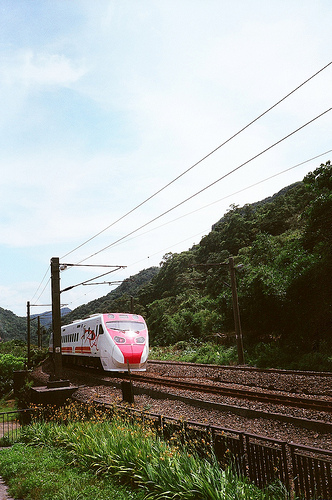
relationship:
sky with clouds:
[4, 7, 302, 143] [17, 43, 98, 95]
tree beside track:
[235, 240, 316, 346] [168, 353, 330, 437]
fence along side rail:
[80, 399, 330, 495] [139, 370, 330, 422]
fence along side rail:
[0, 399, 332, 499] [64, 359, 155, 384]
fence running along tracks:
[0, 399, 332, 499] [158, 361, 319, 431]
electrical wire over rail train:
[58, 57, 331, 265] [49, 312, 149, 371]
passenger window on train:
[65, 327, 80, 343] [28, 303, 149, 375]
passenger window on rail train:
[62, 331, 80, 343] [153, 369, 219, 410]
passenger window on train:
[62, 331, 80, 343] [49, 313, 149, 373]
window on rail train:
[105, 321, 144, 331] [49, 312, 150, 367]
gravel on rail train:
[60, 358, 330, 451] [155, 371, 332, 422]